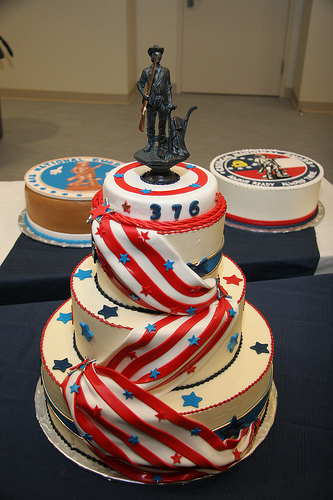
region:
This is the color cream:
[240, 368, 251, 377]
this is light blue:
[189, 398, 197, 406]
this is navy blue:
[255, 344, 261, 350]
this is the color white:
[135, 402, 144, 410]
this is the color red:
[109, 397, 119, 408]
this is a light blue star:
[174, 386, 205, 412]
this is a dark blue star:
[250, 336, 274, 355]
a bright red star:
[149, 403, 168, 422]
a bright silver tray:
[12, 334, 299, 490]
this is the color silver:
[71, 453, 80, 458]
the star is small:
[106, 386, 250, 493]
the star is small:
[96, 337, 151, 432]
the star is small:
[134, 403, 196, 487]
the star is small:
[79, 340, 176, 470]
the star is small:
[51, 299, 161, 399]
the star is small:
[91, 379, 167, 459]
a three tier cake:
[20, 147, 281, 483]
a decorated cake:
[19, 151, 129, 242]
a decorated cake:
[208, 143, 322, 232]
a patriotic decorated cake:
[31, 154, 280, 486]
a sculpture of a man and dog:
[131, 40, 193, 185]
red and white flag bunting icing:
[67, 212, 256, 482]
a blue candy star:
[177, 389, 203, 409]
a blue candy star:
[248, 338, 268, 354]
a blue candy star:
[50, 353, 72, 375]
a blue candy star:
[56, 310, 73, 325]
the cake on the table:
[36, 36, 285, 469]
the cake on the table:
[12, 155, 114, 257]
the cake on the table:
[204, 135, 331, 246]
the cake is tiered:
[28, 44, 288, 494]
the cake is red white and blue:
[39, 44, 291, 487]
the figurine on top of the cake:
[128, 36, 200, 187]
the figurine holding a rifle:
[137, 39, 209, 187]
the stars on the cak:
[106, 233, 205, 362]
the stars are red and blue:
[110, 247, 214, 340]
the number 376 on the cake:
[134, 198, 220, 225]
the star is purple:
[170, 381, 263, 445]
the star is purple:
[177, 380, 213, 431]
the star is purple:
[153, 362, 241, 481]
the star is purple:
[170, 351, 217, 461]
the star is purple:
[162, 372, 229, 430]